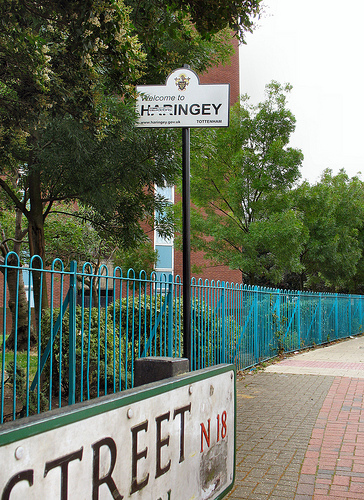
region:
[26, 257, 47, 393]
blue metal fence panel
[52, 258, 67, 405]
blue metal fence panel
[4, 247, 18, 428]
blue metal fence panel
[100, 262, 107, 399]
blue metal fence panel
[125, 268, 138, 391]
blue metal fence panel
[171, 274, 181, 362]
blue metal fence panel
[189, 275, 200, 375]
blue metal fence panel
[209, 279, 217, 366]
blue metal fence panel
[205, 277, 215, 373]
blue metal fence panel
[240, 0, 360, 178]
cloud covered daytime sky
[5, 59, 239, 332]
brick wall on building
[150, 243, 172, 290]
blue panels on wall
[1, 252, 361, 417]
blue metal fence along sidewalk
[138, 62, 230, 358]
sign on black pole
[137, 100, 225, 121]
black word on white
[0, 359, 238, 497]
sign with green trim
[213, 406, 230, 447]
red numbers on sign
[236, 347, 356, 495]
bricks in sidewalk surface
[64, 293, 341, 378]
green bushes behind fence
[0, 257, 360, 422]
this is a fence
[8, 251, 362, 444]
the fence is blue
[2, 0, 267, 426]
this is a tree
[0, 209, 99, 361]
this is a tree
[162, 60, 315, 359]
this is a tree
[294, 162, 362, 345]
this is a tree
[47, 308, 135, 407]
this is a tree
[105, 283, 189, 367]
this is a tree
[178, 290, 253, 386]
this is a tree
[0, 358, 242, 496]
this is a wall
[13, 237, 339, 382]
iron fence painted blue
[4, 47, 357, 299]
trees with bright green leaves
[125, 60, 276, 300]
welcome to haringey sign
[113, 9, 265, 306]
red brick building with white windows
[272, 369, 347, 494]
bricks on side walk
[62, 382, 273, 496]
white street sign with green border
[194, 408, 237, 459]
red lettering on street sign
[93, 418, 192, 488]
black lettering on street sign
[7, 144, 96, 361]
tall brown trunk of tree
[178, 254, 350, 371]
blue fence around brick building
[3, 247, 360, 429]
a light blue metal fence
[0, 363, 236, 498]
a large street sign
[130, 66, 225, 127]
a large white sign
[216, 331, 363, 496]
a brick paved sidewalk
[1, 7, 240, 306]
a tall red brick building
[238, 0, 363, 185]
an overcast white sky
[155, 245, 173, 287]
a building double hung window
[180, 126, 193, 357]
a tall black metal pole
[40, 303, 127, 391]
a small green bush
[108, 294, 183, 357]
a small green bush